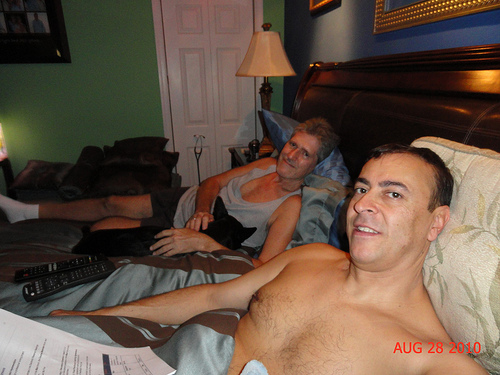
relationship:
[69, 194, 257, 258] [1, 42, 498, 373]
black dog laying on bed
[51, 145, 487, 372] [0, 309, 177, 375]
man has paper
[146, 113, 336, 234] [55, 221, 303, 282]
man holds dog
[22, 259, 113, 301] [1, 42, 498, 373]
remote control on bed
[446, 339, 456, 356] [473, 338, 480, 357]
two next to zero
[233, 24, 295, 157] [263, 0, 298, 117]
lamp in corner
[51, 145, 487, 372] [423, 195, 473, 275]
man who are laying in bed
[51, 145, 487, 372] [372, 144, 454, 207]
man has brown hair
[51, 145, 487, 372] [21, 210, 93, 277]
man wearing socks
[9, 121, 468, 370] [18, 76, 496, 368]
two people on bed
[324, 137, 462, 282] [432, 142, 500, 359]
head on pillow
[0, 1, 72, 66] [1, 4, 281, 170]
frame on wall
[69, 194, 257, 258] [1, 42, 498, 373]
black dog on bed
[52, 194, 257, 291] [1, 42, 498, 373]
black dog on bed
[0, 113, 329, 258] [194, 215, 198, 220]
man wearing a wedding ring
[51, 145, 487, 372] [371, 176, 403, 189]
man has thick eyebrows